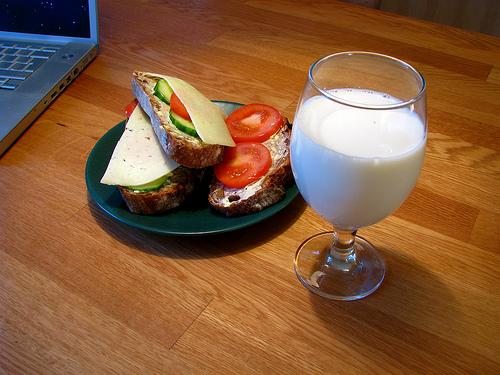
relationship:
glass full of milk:
[287, 48, 429, 304] [289, 86, 427, 230]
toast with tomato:
[207, 102, 293, 220] [213, 101, 285, 191]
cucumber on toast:
[154, 75, 202, 137] [130, 68, 226, 171]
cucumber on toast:
[121, 172, 172, 192] [116, 97, 205, 218]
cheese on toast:
[144, 67, 237, 150] [130, 68, 226, 171]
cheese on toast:
[97, 98, 183, 188] [116, 97, 205, 218]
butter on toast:
[211, 126, 289, 208] [207, 102, 293, 220]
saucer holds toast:
[83, 99, 301, 240] [207, 102, 293, 220]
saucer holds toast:
[83, 99, 301, 240] [130, 68, 226, 171]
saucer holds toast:
[83, 99, 301, 240] [116, 97, 205, 218]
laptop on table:
[0, 1, 103, 161] [0, 1, 498, 373]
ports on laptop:
[41, 66, 81, 106] [0, 1, 103, 161]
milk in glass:
[289, 86, 427, 230] [287, 48, 429, 304]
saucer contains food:
[83, 99, 301, 240] [99, 69, 297, 221]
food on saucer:
[99, 69, 297, 221] [83, 99, 301, 240]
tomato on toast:
[213, 101, 285, 191] [207, 102, 293, 220]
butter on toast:
[209, 122, 290, 210] [207, 102, 293, 220]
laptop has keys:
[0, 1, 103, 161] [0, 39, 61, 93]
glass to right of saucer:
[287, 48, 429, 304] [83, 99, 301, 240]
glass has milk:
[287, 48, 429, 304] [289, 86, 427, 230]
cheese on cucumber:
[144, 67, 237, 150] [154, 75, 202, 137]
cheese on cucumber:
[97, 98, 183, 188] [121, 172, 172, 192]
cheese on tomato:
[144, 67, 237, 150] [166, 89, 192, 124]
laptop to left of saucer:
[0, 1, 103, 161] [83, 99, 301, 240]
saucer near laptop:
[83, 99, 301, 240] [0, 1, 103, 161]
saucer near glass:
[83, 99, 301, 240] [287, 48, 429, 304]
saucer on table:
[83, 99, 301, 240] [0, 1, 498, 373]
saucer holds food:
[83, 99, 301, 240] [99, 69, 297, 221]